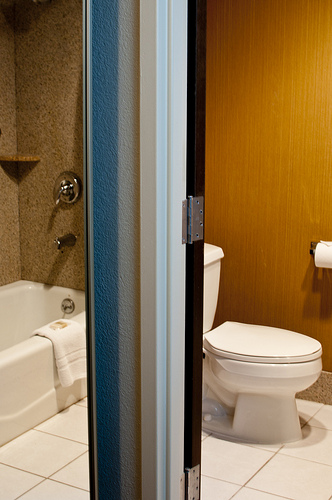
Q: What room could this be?
A: It is a bathroom.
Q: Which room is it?
A: It is a bathroom.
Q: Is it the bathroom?
A: Yes, it is the bathroom.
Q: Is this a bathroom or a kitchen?
A: It is a bathroom.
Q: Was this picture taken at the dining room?
A: No, the picture was taken in the bathroom.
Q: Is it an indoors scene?
A: Yes, it is indoors.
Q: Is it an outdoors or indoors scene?
A: It is indoors.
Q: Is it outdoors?
A: No, it is indoors.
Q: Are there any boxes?
A: No, there are no boxes.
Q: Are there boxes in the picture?
A: No, there are no boxes.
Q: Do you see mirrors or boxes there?
A: No, there are no boxes or mirrors.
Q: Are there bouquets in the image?
A: No, there are no bouquets.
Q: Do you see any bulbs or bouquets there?
A: No, there are no bouquets or bulbs.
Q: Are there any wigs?
A: No, there are no wigs.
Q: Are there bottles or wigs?
A: No, there are no wigs or bottles.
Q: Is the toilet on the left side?
A: No, the toilet is on the right of the image.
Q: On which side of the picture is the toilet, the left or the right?
A: The toilet is on the right of the image.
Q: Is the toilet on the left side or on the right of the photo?
A: The toilet is on the right of the image.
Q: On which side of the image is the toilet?
A: The toilet is on the right of the image.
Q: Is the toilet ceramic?
A: Yes, the toilet is ceramic.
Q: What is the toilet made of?
A: The toilet is made of porcelain.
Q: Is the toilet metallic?
A: No, the toilet is ceramic.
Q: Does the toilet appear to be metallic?
A: No, the toilet is ceramic.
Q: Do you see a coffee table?
A: No, there are no coffee tables.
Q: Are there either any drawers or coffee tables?
A: No, there are no coffee tables or drawers.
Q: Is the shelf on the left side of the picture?
A: Yes, the shelf is on the left of the image.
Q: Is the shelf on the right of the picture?
A: No, the shelf is on the left of the image.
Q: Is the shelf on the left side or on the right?
A: The shelf is on the left of the image.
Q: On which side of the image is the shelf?
A: The shelf is on the left of the image.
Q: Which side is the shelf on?
A: The shelf is on the left of the image.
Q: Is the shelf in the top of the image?
A: Yes, the shelf is in the top of the image.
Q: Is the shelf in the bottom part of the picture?
A: No, the shelf is in the top of the image.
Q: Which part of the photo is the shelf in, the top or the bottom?
A: The shelf is in the top of the image.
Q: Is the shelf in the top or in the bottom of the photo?
A: The shelf is in the top of the image.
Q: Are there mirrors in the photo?
A: No, there are no mirrors.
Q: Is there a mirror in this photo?
A: No, there are no mirrors.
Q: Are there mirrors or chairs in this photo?
A: No, there are no mirrors or chairs.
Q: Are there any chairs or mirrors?
A: No, there are no mirrors or chairs.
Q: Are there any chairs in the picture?
A: No, there are no chairs.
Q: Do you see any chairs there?
A: No, there are no chairs.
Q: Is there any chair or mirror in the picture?
A: No, there are no chairs or mirrors.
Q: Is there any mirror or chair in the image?
A: No, there are no chairs or mirrors.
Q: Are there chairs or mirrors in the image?
A: No, there are no chairs or mirrors.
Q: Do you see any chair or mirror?
A: No, there are no chairs or mirrors.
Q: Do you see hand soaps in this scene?
A: No, there are no hand soaps.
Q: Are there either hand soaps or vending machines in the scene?
A: No, there are no hand soaps or vending machines.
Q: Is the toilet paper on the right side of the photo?
A: Yes, the toilet paper is on the right of the image.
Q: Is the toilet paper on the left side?
A: No, the toilet paper is on the right of the image.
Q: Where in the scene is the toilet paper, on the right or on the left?
A: The toilet paper is on the right of the image.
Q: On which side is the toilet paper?
A: The toilet paper is on the right of the image.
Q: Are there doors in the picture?
A: Yes, there is a door.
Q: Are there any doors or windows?
A: Yes, there is a door.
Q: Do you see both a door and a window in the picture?
A: No, there is a door but no windows.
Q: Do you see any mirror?
A: No, there are no mirrors.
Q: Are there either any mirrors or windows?
A: No, there are no mirrors or windows.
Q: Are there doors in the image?
A: Yes, there is a door.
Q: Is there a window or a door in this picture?
A: Yes, there is a door.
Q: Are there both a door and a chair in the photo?
A: No, there is a door but no chairs.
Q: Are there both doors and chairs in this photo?
A: No, there is a door but no chairs.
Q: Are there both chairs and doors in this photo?
A: No, there is a door but no chairs.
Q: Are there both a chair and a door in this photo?
A: No, there is a door but no chairs.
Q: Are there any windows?
A: No, there are no windows.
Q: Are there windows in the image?
A: No, there are no windows.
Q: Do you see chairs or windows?
A: No, there are no windows or chairs.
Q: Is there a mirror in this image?
A: No, there are no mirrors.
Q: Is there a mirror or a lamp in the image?
A: No, there are no mirrors or lamps.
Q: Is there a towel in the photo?
A: Yes, there is a towel.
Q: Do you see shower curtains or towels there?
A: Yes, there is a towel.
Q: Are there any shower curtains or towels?
A: Yes, there is a towel.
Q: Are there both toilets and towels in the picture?
A: Yes, there are both a towel and a toilet.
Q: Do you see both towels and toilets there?
A: Yes, there are both a towel and a toilet.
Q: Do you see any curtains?
A: No, there are no curtains.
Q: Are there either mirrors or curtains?
A: No, there are no curtains or mirrors.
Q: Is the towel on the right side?
A: No, the towel is on the left of the image.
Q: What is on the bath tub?
A: The towel is on the bath tub.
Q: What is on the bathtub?
A: The towel is on the bath tub.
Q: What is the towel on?
A: The towel is on the bath tub.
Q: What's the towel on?
A: The towel is on the bath tub.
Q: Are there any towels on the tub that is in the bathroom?
A: Yes, there is a towel on the bathtub.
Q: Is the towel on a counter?
A: No, the towel is on a bathtub.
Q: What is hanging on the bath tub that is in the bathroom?
A: The towel is hanging on the bathtub.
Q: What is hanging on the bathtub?
A: The towel is hanging on the bathtub.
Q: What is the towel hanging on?
A: The towel is hanging on the tub.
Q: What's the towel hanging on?
A: The towel is hanging on the tub.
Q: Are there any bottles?
A: No, there are no bottles.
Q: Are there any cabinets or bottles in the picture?
A: No, there are no bottles or cabinets.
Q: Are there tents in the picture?
A: No, there are no tents.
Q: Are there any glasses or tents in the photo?
A: No, there are no tents or glasses.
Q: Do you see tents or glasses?
A: No, there are no tents or glasses.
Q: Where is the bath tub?
A: The bath tub is in the bathroom.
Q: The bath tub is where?
A: The bath tub is in the bathroom.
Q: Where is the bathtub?
A: The bath tub is in the bathroom.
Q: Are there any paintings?
A: No, there are no paintings.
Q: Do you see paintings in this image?
A: No, there are no paintings.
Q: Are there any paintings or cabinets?
A: No, there are no paintings or cabinets.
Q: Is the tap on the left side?
A: Yes, the tap is on the left of the image.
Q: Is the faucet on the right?
A: No, the faucet is on the left of the image.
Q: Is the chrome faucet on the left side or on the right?
A: The faucet is on the left of the image.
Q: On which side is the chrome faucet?
A: The faucet is on the left of the image.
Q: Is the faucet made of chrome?
A: Yes, the faucet is made of chrome.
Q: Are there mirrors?
A: No, there are no mirrors.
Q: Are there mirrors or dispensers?
A: No, there are no mirrors or dispensers.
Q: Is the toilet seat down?
A: Yes, the toilet seat is down.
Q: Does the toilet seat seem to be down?
A: Yes, the toilet seat is down.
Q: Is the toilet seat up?
A: No, the toilet seat is down.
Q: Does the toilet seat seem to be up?
A: No, the toilet seat is down.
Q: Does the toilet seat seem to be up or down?
A: The toilet seat is down.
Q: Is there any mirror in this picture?
A: No, there are no mirrors.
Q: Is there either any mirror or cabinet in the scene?
A: No, there are no mirrors or cabinets.